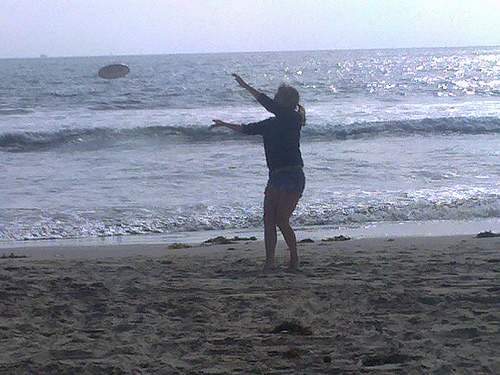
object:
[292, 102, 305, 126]
ponytail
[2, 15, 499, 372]
beach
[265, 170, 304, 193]
shorts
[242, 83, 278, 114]
arms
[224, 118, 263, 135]
arms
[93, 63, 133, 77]
frisbee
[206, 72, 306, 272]
lady